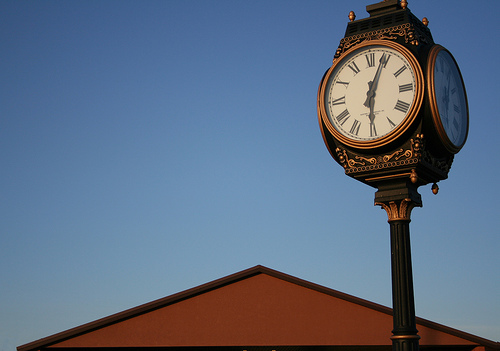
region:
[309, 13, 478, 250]
four clocks on pole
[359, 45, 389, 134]
black hands on clock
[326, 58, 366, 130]
roman numerals on clock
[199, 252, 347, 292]
point on top of roof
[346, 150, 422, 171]
gold decoration under clock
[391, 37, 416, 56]
gold border around clockface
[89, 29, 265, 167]
clear blue daytime sky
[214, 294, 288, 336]
plain red wall under roof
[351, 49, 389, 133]
hands pointing at 6:05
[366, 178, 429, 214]
pedestal under clocks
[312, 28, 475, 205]
A multiple faced clock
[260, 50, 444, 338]
clock set up on a pole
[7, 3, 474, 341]
Clock set up high in the air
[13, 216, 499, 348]
Clock extends above the roof top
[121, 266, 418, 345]
Brown rooftop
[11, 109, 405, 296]
The sky is shades of blue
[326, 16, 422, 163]
It is six'o five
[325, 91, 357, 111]
The clock uses roman numerals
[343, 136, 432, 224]
The clock has gold ornament work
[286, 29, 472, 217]
This side of the clock is facing the sun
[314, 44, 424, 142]
face of the clock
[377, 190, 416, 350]
pole for the clock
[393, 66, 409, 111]
some of the roman numerals on clock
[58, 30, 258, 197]
portion of the blue sky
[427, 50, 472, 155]
clock face on the side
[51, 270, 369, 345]
a triangular shaped roof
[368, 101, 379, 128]
small hand on face of clock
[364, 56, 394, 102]
large hand on face of clock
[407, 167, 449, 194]
decorative pieces hanging from clock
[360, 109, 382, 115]
small letter on clock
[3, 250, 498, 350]
Roof of a building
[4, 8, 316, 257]
Sky is blue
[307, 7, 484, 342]
Clock in a pole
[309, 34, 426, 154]
Clock has roman numerals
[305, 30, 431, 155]
Time display in the clock is 6:05 pm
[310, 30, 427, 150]
Roman numerals are black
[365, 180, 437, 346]
Pole support a clock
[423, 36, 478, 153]
Clock on side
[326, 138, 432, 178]
Intricate decorations under clock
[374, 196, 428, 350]
Pole has decorations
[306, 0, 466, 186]
tall four faced outdoor clock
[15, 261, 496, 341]
peak of roof on a building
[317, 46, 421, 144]
clock face with roman numerals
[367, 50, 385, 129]
hands of clock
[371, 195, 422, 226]
gold detail at top of pole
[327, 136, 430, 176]
decorative gold scroll work on clock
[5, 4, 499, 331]
brilliant blue clear sky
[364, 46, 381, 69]
roman numeral for 12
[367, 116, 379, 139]
roman numeral for 6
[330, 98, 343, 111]
roman numeral for 9